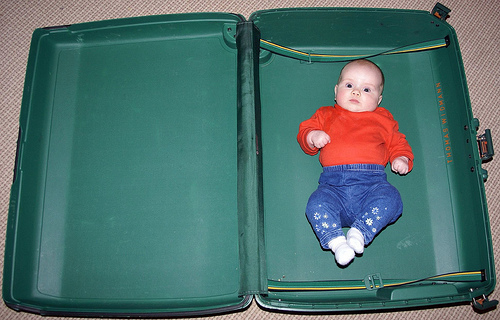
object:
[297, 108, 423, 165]
top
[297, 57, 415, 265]
baby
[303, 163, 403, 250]
jeans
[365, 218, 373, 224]
flower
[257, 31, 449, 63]
strap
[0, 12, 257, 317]
top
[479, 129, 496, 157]
handle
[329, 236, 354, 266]
sock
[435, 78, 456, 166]
writing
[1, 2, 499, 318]
capeting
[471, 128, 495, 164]
lock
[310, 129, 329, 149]
hand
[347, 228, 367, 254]
sock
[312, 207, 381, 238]
pattern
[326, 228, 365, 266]
socks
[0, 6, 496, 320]
suitcase